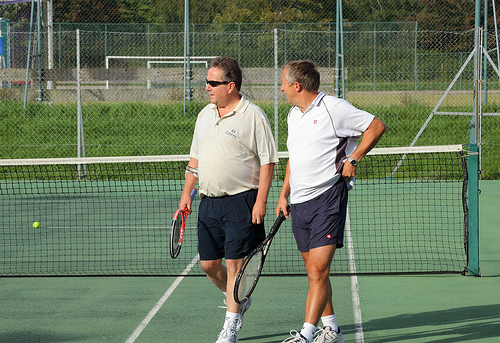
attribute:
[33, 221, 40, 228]
tennis ball — yellow, green, round, small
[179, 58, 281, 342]
man — standing, light skinned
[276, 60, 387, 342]
man — standing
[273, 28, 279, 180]
post — metal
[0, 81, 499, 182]
grass — green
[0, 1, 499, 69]
trees — leafy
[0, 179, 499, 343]
ground — green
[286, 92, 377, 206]
polo shirt — white